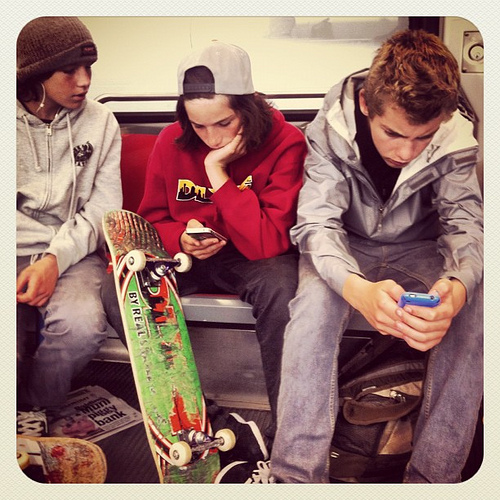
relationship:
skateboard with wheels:
[98, 207, 239, 484] [122, 247, 237, 466]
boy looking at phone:
[306, 60, 483, 341] [385, 274, 465, 358]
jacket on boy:
[292, 103, 484, 277] [297, 17, 494, 440]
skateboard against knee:
[98, 207, 239, 484] [97, 267, 129, 315]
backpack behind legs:
[339, 331, 416, 481] [272, 288, 347, 485]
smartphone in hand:
[182, 225, 229, 246] [177, 217, 229, 261]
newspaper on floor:
[66, 382, 149, 445] [15, 387, 385, 486]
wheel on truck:
[127, 249, 147, 270] [144, 252, 176, 268]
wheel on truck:
[171, 250, 188, 277] [144, 252, 176, 268]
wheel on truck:
[212, 430, 234, 451] [188, 430, 223, 456]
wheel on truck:
[167, 438, 189, 463] [188, 430, 223, 456]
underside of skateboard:
[118, 218, 217, 480] [102, 209, 224, 481]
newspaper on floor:
[46, 382, 143, 444] [70, 359, 273, 483]